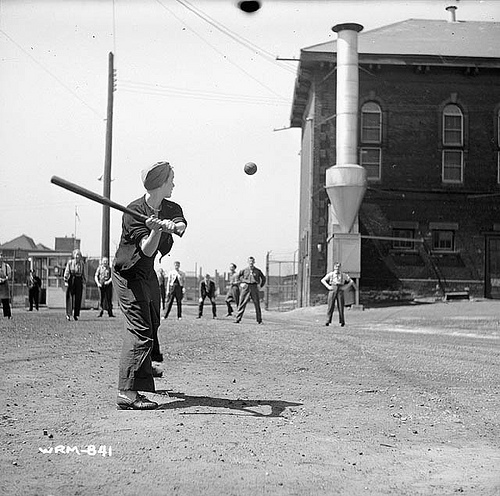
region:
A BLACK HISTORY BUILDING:
[285, 1, 493, 299]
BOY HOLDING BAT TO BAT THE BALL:
[45, 160, 185, 410]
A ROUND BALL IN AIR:
[240, 160, 260, 172]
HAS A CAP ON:
[135, 156, 180, 187]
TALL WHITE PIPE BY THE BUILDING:
[320, 12, 362, 312]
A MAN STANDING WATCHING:
[320, 260, 350, 325]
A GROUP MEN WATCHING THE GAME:
[0, 247, 265, 327]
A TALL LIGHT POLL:
[92, 47, 119, 312]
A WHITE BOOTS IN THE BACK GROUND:
[20, 237, 87, 303]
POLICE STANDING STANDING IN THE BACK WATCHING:
[21, 266, 42, 312]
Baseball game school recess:
[46, 144, 261, 418]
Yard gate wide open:
[260, 244, 307, 317]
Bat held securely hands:
[43, 174, 199, 233]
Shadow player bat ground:
[108, 370, 313, 429]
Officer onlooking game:
[19, 265, 51, 312]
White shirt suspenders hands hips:
[320, 260, 358, 329]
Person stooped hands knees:
[195, 270, 222, 322]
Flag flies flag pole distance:
[63, 200, 90, 249]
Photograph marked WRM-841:
[31, 427, 129, 467]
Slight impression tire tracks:
[278, 320, 498, 430]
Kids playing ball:
[15, 154, 366, 410]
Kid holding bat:
[50, 150, 205, 435]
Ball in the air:
[224, 134, 268, 199]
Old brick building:
[288, 8, 498, 278]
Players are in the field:
[20, 240, 310, 325]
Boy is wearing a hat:
[113, 145, 189, 220]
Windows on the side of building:
[353, 75, 496, 160]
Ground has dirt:
[33, 307, 473, 457]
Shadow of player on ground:
[151, 357, 288, 439]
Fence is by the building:
[250, 238, 302, 316]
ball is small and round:
[229, 158, 268, 183]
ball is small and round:
[229, 138, 292, 222]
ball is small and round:
[232, 150, 271, 197]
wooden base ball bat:
[45, 146, 195, 276]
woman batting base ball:
[95, 157, 200, 444]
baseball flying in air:
[220, 115, 285, 220]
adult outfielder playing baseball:
[230, 252, 270, 327]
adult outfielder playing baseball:
[310, 250, 365, 325]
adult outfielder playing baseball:
[56, 241, 88, 326]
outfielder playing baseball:
[195, 270, 220, 320]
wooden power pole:
[88, 35, 138, 310]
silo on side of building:
[320, 15, 382, 320]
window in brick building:
[431, 85, 474, 205]